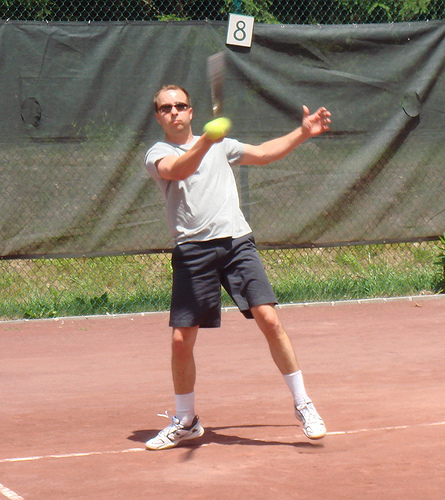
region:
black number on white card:
[224, 8, 255, 58]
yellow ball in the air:
[206, 114, 233, 145]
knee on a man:
[167, 333, 199, 354]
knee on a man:
[259, 312, 282, 332]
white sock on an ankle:
[284, 364, 313, 409]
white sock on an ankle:
[170, 390, 200, 421]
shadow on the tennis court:
[200, 414, 282, 451]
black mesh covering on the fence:
[340, 37, 443, 233]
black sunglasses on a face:
[157, 101, 198, 116]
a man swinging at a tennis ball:
[130, 85, 344, 496]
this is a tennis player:
[119, 76, 322, 438]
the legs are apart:
[185, 318, 294, 410]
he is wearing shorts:
[192, 245, 250, 298]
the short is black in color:
[183, 244, 216, 307]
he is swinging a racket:
[160, 80, 255, 157]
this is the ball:
[204, 113, 226, 136]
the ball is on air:
[204, 114, 225, 134]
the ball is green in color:
[202, 114, 232, 140]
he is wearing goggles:
[160, 98, 191, 111]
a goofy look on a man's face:
[154, 84, 192, 137]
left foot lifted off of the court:
[285, 368, 326, 439]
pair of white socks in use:
[173, 369, 311, 425]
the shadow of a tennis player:
[128, 421, 323, 464]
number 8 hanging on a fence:
[226, 12, 253, 45]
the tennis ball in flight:
[202, 112, 233, 143]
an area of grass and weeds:
[0, 223, 443, 322]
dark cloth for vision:
[3, 15, 441, 259]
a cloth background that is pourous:
[2, 18, 442, 259]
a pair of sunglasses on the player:
[152, 101, 195, 115]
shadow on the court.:
[215, 424, 240, 444]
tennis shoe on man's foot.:
[289, 407, 326, 440]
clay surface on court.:
[284, 473, 355, 481]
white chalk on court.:
[8, 489, 16, 499]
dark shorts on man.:
[183, 271, 206, 302]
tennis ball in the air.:
[204, 117, 228, 139]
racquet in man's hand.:
[203, 54, 228, 109]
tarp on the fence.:
[75, 63, 135, 97]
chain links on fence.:
[85, 271, 127, 290]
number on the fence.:
[228, 19, 255, 45]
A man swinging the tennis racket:
[127, 46, 346, 460]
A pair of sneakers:
[144, 399, 330, 454]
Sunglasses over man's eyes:
[149, 98, 198, 118]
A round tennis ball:
[196, 108, 235, 151]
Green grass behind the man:
[3, 249, 442, 318]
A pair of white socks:
[169, 370, 311, 417]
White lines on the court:
[2, 416, 443, 498]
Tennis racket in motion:
[196, 41, 237, 137]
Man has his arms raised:
[135, 77, 333, 190]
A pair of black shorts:
[163, 230, 286, 335]